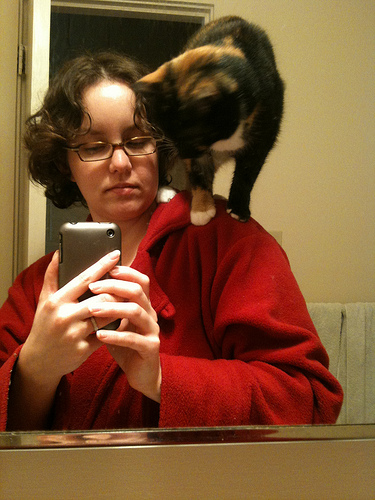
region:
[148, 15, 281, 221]
a cat on the shoulder of the girl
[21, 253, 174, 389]
a couple of white girl hands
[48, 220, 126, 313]
a modern smartphone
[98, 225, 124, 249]
the rear smartphone camera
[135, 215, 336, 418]
the girl in a red rope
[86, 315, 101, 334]
a silver ring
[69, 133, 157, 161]
a brown frame glasses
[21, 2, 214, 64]
the door of the bathroom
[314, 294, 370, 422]
a white towel hanging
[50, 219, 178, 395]
two hands holding a smartphone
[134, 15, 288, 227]
Cat on woman's shoulder.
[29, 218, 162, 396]
Cell phone in woman's hands.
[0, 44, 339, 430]
Woman looking at her cell phone.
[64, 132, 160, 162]
Glasses over woman's eyes.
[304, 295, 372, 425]
Towels hanging on rack.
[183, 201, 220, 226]
White and brown cat paw.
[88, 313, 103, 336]
Ring on woman's finger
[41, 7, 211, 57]
Open doorway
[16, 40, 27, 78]
Top hinge of door.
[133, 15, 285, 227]
Black, brown and white cat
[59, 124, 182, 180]
woman is wearing glasses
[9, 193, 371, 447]
woman's robe is red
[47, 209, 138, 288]
woman is holding a phone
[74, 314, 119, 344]
woman wearing a ring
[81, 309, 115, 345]
the ring is silver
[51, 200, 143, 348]
the phone is gray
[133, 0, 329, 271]
cat sitting on woman's shoulder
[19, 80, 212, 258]
woman's hair is brown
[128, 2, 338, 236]
the cat is orange and black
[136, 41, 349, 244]
cat is looking at woman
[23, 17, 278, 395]
lady taking a picture with cat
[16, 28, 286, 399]
lady taking a mirror selfie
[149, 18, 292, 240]
cat perched on top of lady's shoulder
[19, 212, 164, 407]
engaged woman taking a picture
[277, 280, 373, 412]
towels hanging on a towel rack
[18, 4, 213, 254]
open door behind the woman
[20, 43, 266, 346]
woman taking a picture with her phone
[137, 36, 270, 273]
cat looking down from woman's shoulder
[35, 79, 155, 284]
woman wearing glasses looking at her phone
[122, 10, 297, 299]
calico cat sitting on a woman's shoulder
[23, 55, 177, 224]
the woman has long hair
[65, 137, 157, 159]
the woman is wearing glasses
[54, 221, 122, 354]
the woman is holding a cell phone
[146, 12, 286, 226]
the cat is on the woman's shoulders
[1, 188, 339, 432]
the woman is wearing a robe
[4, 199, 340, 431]
the robe is red in color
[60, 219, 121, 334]
the cell phone is grey in color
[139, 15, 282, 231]
the cat is looking at the cell phone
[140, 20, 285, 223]
the cat is brown in color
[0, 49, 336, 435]
the woman is taking a selfie